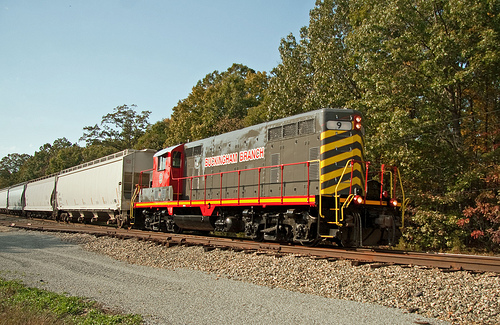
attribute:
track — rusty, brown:
[1, 210, 499, 274]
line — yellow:
[339, 195, 402, 209]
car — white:
[57, 147, 154, 221]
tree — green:
[170, 64, 262, 148]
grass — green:
[1, 278, 145, 324]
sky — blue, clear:
[2, 2, 325, 169]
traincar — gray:
[22, 175, 54, 218]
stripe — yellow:
[320, 133, 358, 153]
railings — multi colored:
[335, 159, 404, 206]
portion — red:
[155, 144, 184, 192]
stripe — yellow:
[135, 197, 316, 207]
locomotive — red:
[127, 106, 405, 249]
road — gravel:
[2, 229, 453, 324]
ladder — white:
[120, 153, 135, 216]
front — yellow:
[325, 107, 405, 247]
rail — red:
[170, 160, 312, 179]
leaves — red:
[459, 174, 499, 244]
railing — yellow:
[335, 159, 349, 217]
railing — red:
[171, 160, 312, 199]